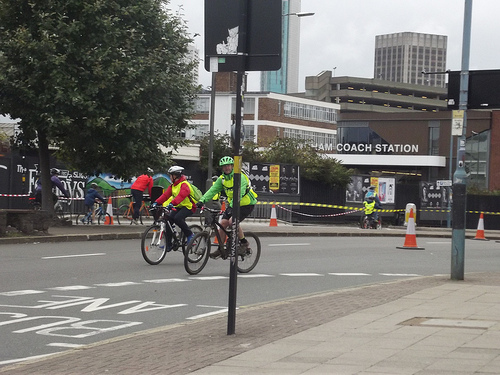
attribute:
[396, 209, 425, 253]
cone — orange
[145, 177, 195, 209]
jacket — red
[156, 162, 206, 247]
boy — little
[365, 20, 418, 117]
building — tall, office building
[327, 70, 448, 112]
garage — very large